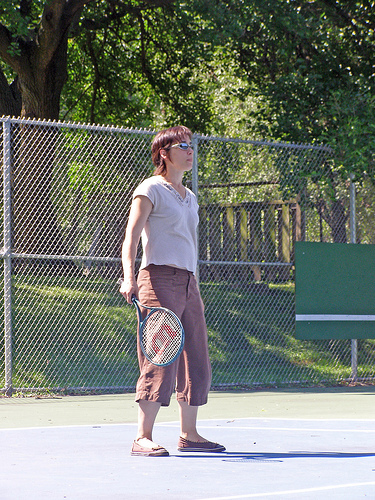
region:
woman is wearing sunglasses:
[163, 140, 194, 148]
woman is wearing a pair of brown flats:
[126, 434, 227, 454]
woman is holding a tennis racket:
[114, 275, 186, 369]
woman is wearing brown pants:
[128, 261, 214, 405]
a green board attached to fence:
[292, 239, 373, 347]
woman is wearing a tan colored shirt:
[130, 170, 205, 272]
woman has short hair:
[151, 122, 195, 178]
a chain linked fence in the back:
[0, 111, 374, 386]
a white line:
[295, 308, 374, 322]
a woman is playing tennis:
[116, 121, 235, 478]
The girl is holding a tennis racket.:
[115, 106, 237, 461]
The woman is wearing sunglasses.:
[109, 122, 232, 468]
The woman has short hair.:
[116, 116, 234, 464]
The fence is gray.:
[0, 107, 374, 393]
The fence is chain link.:
[1, 108, 373, 396]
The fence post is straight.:
[1, 112, 19, 400]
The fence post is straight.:
[340, 146, 361, 383]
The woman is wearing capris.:
[108, 121, 230, 460]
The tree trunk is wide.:
[0, 1, 88, 280]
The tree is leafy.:
[1, 1, 374, 224]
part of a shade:
[286, 443, 295, 452]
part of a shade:
[259, 435, 292, 480]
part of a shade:
[291, 439, 317, 469]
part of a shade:
[245, 449, 260, 468]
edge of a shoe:
[137, 429, 158, 450]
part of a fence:
[276, 348, 287, 359]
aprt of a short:
[188, 382, 202, 396]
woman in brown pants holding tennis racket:
[118, 120, 235, 459]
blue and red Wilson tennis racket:
[115, 274, 186, 365]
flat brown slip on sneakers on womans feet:
[133, 434, 229, 458]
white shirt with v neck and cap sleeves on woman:
[134, 170, 206, 271]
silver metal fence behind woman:
[5, 107, 371, 392]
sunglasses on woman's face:
[170, 140, 196, 150]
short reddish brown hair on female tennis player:
[148, 122, 193, 171]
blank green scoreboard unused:
[285, 234, 372, 380]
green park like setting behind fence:
[7, 1, 371, 388]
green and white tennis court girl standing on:
[4, 391, 370, 496]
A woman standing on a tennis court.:
[5, 125, 371, 496]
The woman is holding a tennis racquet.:
[113, 274, 182, 364]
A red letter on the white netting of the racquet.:
[144, 317, 174, 356]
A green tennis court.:
[1, 386, 372, 496]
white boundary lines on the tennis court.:
[0, 417, 369, 494]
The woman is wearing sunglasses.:
[160, 137, 195, 151]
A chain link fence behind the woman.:
[0, 114, 373, 388]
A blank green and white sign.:
[293, 240, 371, 341]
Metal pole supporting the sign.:
[350, 338, 357, 379]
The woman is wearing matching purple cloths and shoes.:
[121, 174, 226, 457]